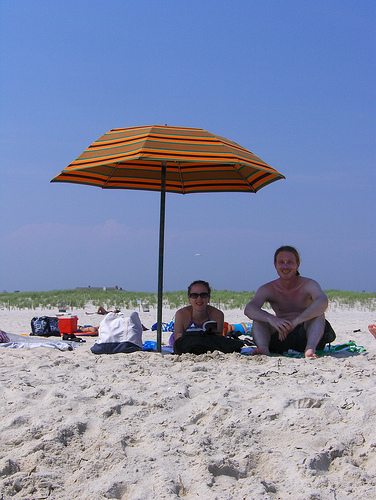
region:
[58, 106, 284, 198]
multi colored umbrella on beach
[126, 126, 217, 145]
yellow and black stripes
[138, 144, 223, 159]
blue and yellow stripes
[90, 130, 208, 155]
striped umbrella in sand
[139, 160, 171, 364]
brown umbrella pole in sand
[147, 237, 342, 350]
two people sitting under umbrella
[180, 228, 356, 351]
two people sitting on the beach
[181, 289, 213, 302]
black sunglasses on woman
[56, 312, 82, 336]
red cooler on the sand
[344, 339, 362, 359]
green towel on the sand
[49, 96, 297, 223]
an orange and black umbrella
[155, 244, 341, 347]
two people under an umbrella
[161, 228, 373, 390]
two people on the beach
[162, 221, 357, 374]
a man and woman on beach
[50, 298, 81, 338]
a red and white cooler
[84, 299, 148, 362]
a white and blue bag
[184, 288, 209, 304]
sunglasses on her face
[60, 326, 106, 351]
a black sandal on beach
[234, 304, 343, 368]
black shorts on man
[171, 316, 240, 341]
a book in front of her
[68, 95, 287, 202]
a large umbrella in top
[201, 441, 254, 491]
whole in the sand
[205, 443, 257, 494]
a foot mark in sand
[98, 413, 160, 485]
a foot mark of man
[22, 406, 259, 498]
a few darks in sand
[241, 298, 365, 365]
a man wearing shorts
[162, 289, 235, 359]
a woman wearing vest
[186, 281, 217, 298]
spects of the girl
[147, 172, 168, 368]
a iron rod in sand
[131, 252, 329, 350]
two people sitting in sand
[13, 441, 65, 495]
Small imprints in the sand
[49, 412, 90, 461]
Small imprints in the sand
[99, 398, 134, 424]
Small imprints in the sand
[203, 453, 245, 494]
Small imprints in the sand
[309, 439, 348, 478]
Small imprints in the sand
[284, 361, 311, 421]
Small imprints in the sand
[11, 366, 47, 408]
Small imprints in the sand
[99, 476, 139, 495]
Small imprints in the sand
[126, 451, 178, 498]
Small imprints in the sand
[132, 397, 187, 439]
Small imprints in the sand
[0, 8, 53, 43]
part of the clear blue sky